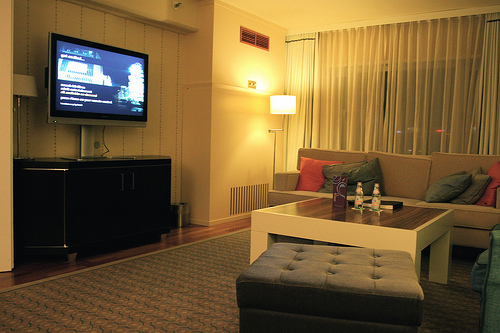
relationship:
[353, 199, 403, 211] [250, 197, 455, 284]
items on table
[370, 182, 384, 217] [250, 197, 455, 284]
items on table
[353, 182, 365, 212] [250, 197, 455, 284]
items on table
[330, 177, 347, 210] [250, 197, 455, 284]
items on table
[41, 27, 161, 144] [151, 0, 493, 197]
television hanging on wall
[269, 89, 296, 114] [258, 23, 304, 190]
lamp in corner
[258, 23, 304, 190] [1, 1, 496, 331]
corner of room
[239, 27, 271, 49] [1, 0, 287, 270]
vent on top of wall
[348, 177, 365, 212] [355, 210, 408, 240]
bottled drink on table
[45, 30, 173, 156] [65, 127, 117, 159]
tv on stand